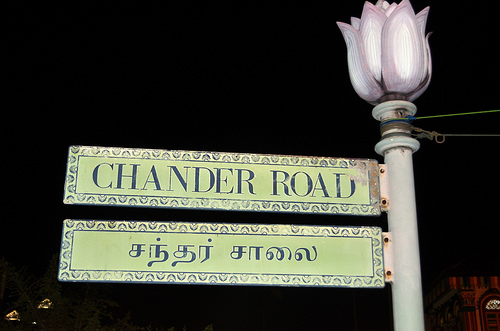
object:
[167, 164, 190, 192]
n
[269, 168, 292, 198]
r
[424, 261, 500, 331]
building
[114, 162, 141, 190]
h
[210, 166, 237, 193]
e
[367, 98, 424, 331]
metal pole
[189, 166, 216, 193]
d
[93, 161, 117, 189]
c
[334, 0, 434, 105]
top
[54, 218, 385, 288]
sign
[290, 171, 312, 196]
o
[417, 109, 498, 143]
wires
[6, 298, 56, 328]
tree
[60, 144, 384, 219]
sign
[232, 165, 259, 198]
letter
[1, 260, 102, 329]
house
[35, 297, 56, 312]
light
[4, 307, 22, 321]
light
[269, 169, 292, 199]
letter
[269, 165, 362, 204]
road